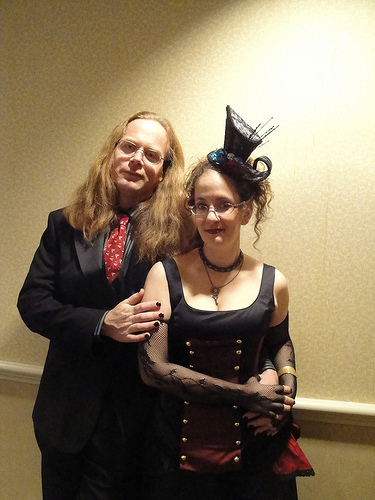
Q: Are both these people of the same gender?
A: No, they are both male and female.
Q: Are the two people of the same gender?
A: No, they are both male and female.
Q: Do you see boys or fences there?
A: No, there are no fences or boys.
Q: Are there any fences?
A: No, there are no fences.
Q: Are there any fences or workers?
A: No, there are no fences or workers.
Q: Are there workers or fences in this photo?
A: No, there are no fences or workers.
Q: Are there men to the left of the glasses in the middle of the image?
A: Yes, there is a man to the left of the glasses.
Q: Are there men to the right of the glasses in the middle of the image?
A: No, the man is to the left of the glasses.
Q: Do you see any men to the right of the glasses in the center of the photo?
A: No, the man is to the left of the glasses.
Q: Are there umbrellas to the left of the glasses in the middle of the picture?
A: No, there is a man to the left of the glasses.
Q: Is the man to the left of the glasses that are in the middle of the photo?
A: Yes, the man is to the left of the glasses.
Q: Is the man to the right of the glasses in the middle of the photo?
A: No, the man is to the left of the glasses.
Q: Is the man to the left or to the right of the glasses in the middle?
A: The man is to the left of the glasses.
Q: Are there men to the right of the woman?
A: No, the man is to the left of the woman.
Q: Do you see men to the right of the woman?
A: No, the man is to the left of the woman.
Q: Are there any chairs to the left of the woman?
A: No, there is a man to the left of the woman.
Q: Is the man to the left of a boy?
A: No, the man is to the left of the woman.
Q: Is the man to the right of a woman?
A: No, the man is to the left of a woman.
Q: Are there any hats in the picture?
A: Yes, there is a hat.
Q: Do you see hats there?
A: Yes, there is a hat.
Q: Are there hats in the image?
A: Yes, there is a hat.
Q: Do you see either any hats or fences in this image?
A: Yes, there is a hat.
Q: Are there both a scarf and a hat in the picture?
A: No, there is a hat but no scarves.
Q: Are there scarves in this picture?
A: No, there are no scarves.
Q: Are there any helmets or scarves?
A: No, there are no scarves or helmets.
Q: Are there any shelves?
A: No, there are no shelves.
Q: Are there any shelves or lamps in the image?
A: No, there are no shelves or lamps.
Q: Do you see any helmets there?
A: No, there are no helmets.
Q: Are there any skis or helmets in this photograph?
A: No, there are no helmets or skis.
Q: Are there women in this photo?
A: Yes, there is a woman.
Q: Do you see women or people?
A: Yes, there is a woman.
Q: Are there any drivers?
A: No, there are no drivers.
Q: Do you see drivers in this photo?
A: No, there are no drivers.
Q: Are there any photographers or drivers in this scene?
A: No, there are no drivers or photographers.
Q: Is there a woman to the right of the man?
A: Yes, there is a woman to the right of the man.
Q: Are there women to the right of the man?
A: Yes, there is a woman to the right of the man.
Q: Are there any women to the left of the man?
A: No, the woman is to the right of the man.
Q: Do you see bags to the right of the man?
A: No, there is a woman to the right of the man.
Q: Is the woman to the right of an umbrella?
A: No, the woman is to the right of the man.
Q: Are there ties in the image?
A: Yes, there is a tie.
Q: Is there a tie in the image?
A: Yes, there is a tie.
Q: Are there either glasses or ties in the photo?
A: Yes, there is a tie.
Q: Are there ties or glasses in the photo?
A: Yes, there is a tie.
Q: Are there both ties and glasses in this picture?
A: Yes, there are both a tie and glasses.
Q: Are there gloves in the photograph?
A: Yes, there are gloves.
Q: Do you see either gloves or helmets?
A: Yes, there are gloves.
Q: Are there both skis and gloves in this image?
A: No, there are gloves but no skis.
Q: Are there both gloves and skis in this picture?
A: No, there are gloves but no skis.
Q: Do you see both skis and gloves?
A: No, there are gloves but no skis.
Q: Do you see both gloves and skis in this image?
A: No, there are gloves but no skis.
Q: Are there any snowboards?
A: No, there are no snowboards.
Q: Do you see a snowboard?
A: No, there are no snowboards.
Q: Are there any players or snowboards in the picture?
A: No, there are no snowboards or players.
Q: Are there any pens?
A: No, there are no pens.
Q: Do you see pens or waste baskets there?
A: No, there are no pens or waste baskets.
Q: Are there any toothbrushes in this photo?
A: No, there are no toothbrushes.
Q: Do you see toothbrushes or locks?
A: No, there are no toothbrushes or locks.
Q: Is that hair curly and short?
A: No, the hair is curly but long.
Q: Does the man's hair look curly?
A: Yes, the hair is curly.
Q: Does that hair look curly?
A: Yes, the hair is curly.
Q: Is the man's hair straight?
A: No, the hair is curly.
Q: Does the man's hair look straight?
A: No, the hair is curly.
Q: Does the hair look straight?
A: No, the hair is curly.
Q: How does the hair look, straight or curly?
A: The hair is curly.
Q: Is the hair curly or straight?
A: The hair is curly.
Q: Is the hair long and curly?
A: Yes, the hair is long and curly.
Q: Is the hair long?
A: Yes, the hair is long.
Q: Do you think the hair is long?
A: Yes, the hair is long.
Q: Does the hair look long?
A: Yes, the hair is long.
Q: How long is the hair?
A: The hair is long.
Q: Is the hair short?
A: No, the hair is long.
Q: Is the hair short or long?
A: The hair is long.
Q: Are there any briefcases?
A: No, there are no briefcases.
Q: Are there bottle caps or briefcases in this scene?
A: No, there are no briefcases or bottle caps.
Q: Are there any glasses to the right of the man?
A: Yes, there are glasses to the right of the man.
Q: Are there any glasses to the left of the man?
A: No, the glasses are to the right of the man.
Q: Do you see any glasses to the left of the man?
A: No, the glasses are to the right of the man.